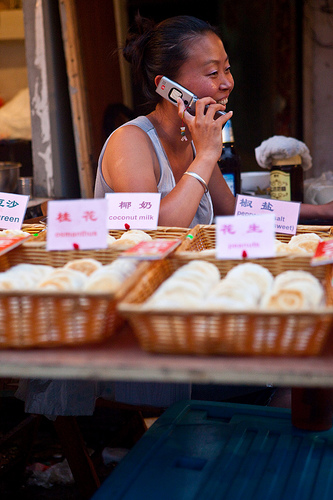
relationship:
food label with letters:
[235, 193, 300, 237] [236, 196, 272, 209]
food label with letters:
[45, 198, 110, 252] [217, 220, 263, 233]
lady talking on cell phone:
[92, 17, 333, 229] [154, 72, 228, 131]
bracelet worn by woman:
[185, 166, 206, 189] [88, 17, 266, 214]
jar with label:
[270, 156, 303, 202] [267, 168, 292, 201]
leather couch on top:
[255, 134, 312, 170] [273, 156, 301, 164]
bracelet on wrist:
[184, 170, 209, 194] [192, 149, 222, 164]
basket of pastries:
[132, 302, 278, 352] [144, 256, 219, 313]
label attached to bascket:
[214, 212, 277, 260] [175, 224, 331, 281]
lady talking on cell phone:
[92, 17, 333, 229] [152, 76, 227, 129]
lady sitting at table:
[92, 17, 333, 229] [1, 220, 331, 387]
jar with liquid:
[270, 156, 302, 202] [259, 140, 314, 211]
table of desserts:
[20, 335, 330, 409] [0, 219, 332, 358]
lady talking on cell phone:
[97, 17, 235, 222] [157, 78, 226, 123]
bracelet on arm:
[184, 170, 209, 194] [156, 96, 237, 232]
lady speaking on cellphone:
[92, 17, 333, 229] [153, 75, 193, 113]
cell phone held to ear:
[153, 76, 228, 133] [151, 67, 167, 90]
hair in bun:
[109, 5, 223, 118] [113, 24, 166, 71]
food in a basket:
[147, 253, 319, 321] [112, 253, 331, 359]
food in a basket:
[63, 253, 102, 269] [171, 221, 331, 265]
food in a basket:
[278, 243, 314, 258] [1, 247, 147, 343]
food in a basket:
[111, 236, 137, 251] [3, 213, 49, 239]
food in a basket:
[2, 270, 18, 291] [30, 220, 191, 236]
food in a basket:
[283, 243, 314, 258] [171, 221, 331, 265]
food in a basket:
[293, 233, 325, 254] [175, 220, 331, 255]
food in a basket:
[262, 283, 311, 309] [122, 256, 331, 350]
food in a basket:
[227, 259, 270, 282] [25, 223, 186, 241]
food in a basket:
[180, 258, 219, 274] [1, 247, 147, 343]